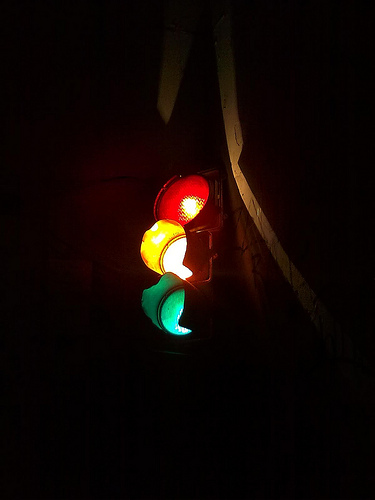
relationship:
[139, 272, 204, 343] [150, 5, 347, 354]
green light on pole